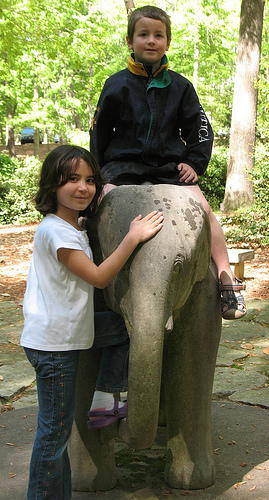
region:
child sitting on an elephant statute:
[86, 8, 255, 310]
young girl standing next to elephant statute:
[22, 144, 156, 493]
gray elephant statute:
[73, 179, 237, 492]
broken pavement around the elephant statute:
[2, 301, 267, 493]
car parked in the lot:
[18, 125, 39, 143]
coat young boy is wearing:
[88, 71, 216, 165]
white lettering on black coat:
[198, 104, 210, 140]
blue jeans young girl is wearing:
[25, 346, 86, 498]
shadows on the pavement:
[82, 369, 256, 497]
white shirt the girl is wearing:
[21, 215, 101, 346]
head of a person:
[118, 10, 190, 61]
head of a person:
[6, 140, 121, 228]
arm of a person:
[57, 234, 141, 291]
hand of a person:
[124, 217, 187, 235]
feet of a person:
[212, 264, 259, 322]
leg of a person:
[19, 342, 97, 485]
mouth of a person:
[74, 189, 95, 204]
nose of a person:
[75, 182, 99, 196]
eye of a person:
[68, 168, 84, 185]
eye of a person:
[78, 171, 103, 191]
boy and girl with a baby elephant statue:
[21, 6, 214, 497]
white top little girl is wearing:
[18, 213, 94, 351]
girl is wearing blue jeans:
[23, 347, 83, 498]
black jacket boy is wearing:
[88, 68, 212, 180]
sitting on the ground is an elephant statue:
[96, 183, 223, 490]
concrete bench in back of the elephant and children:
[225, 248, 254, 281]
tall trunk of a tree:
[220, 36, 256, 212]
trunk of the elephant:
[123, 279, 166, 453]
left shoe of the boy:
[220, 289, 247, 317]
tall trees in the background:
[0, 1, 266, 145]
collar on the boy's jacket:
[125, 58, 187, 76]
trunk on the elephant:
[126, 269, 162, 458]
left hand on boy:
[175, 160, 203, 188]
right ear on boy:
[123, 32, 136, 54]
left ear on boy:
[165, 38, 178, 48]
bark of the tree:
[224, 0, 259, 205]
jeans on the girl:
[23, 349, 81, 498]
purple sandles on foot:
[85, 400, 131, 431]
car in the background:
[21, 128, 43, 142]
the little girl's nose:
[77, 184, 87, 191]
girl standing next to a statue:
[28, 139, 235, 492]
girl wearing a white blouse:
[15, 138, 114, 374]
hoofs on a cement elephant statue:
[67, 417, 220, 493]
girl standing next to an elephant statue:
[22, 145, 222, 490]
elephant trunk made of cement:
[118, 296, 161, 442]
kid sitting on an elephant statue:
[86, 6, 233, 492]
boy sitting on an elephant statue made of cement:
[75, 4, 219, 494]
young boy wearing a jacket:
[78, 4, 218, 160]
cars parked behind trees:
[15, 123, 63, 143]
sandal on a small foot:
[213, 272, 253, 322]